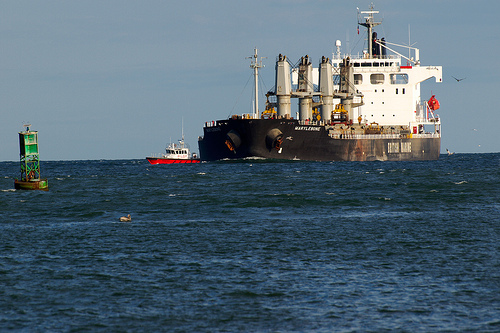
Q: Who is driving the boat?
A: The captain.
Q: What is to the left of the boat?
A: Tugboat.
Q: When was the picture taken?
A: Daytime.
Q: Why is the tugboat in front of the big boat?
A: Pulling it.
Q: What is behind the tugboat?
A: Ship.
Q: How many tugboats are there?
A: One.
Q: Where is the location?
A: Sea.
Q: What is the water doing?
A: Calm.